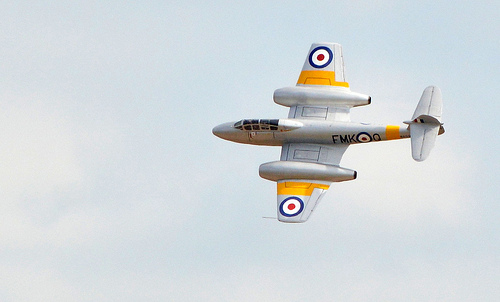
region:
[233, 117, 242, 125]
glass window on plane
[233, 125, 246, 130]
glass window on plane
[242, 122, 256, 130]
glass window on plane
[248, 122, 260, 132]
glass window on plane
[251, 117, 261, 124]
glass window on plane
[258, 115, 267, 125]
glass window on plane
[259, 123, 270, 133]
glass window on plane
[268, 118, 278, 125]
glass window on plane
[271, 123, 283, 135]
glass window on plane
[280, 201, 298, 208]
Blue and white circle on a plane.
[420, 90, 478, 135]
Blue and white circle on a plane.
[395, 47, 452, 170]
tail of the plane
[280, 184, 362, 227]
wing of the plane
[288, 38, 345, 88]
wing of the plane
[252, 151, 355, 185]
engine of the plane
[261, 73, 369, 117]
engine of the plane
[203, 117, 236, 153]
nose of the plane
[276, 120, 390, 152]
middle of the plane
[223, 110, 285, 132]
windshield of the plane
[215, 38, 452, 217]
the plane is flying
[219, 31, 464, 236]
plane in the sky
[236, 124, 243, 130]
glass window on plane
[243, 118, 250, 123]
glass window on plane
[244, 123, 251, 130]
glass window on plane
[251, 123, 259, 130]
glass window on plane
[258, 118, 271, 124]
glass window on plane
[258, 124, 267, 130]
glass window on plane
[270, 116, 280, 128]
glass window on plane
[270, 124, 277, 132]
glass window on plane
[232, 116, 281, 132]
glass windows on plane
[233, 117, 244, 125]
window on an airplane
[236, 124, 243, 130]
window on an airplane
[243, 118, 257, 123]
window on an airplane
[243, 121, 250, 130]
window on an airplane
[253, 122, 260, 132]
window on an airplane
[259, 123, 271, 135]
window on an airplane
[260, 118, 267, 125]
window on an airplane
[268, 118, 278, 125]
window on an airplane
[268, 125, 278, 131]
window on an airplane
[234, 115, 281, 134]
windows on an airplane